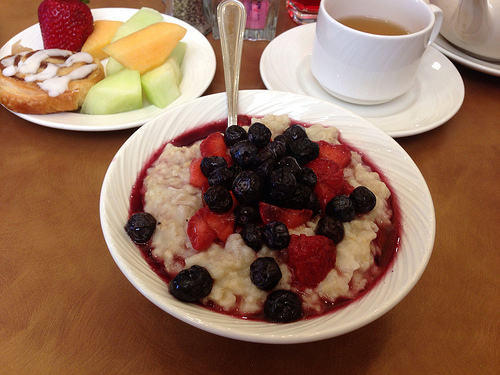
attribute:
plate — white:
[255, 22, 472, 138]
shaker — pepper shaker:
[156, 0, 221, 48]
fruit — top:
[220, 127, 314, 248]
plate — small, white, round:
[6, 16, 210, 130]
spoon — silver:
[200, 12, 283, 151]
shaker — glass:
[166, 0, 211, 36]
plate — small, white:
[0, 5, 216, 130]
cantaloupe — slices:
[83, 70, 143, 116]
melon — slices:
[107, 24, 184, 71]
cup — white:
[308, 2, 448, 101]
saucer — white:
[259, 22, 470, 139]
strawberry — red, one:
[290, 232, 337, 292]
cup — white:
[309, 0, 443, 108]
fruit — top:
[214, 136, 343, 229]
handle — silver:
[212, 0, 253, 129]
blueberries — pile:
[218, 122, 321, 226]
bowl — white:
[93, 83, 441, 337]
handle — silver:
[213, 0, 245, 130]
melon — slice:
[76, 68, 148, 128]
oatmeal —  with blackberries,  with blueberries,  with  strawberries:
[155, 129, 395, 304]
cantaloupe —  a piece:
[100, 20, 186, 71]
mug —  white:
[304, 3, 437, 103]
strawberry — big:
[35, 7, 102, 60]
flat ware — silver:
[198, 2, 260, 147]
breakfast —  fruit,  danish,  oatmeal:
[1, 0, 398, 329]